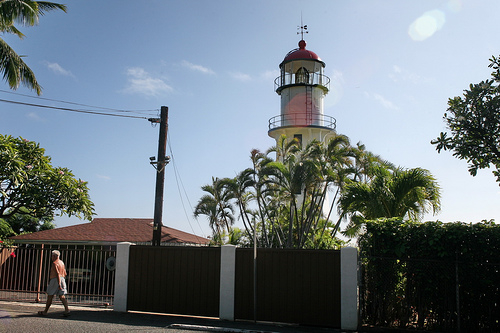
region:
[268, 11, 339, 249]
a light house with a tin red roof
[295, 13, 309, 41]
a weather vane on the top of the light house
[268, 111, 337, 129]
the light house has a balcony around the building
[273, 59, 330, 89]
the light house has a railing around the tower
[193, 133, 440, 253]
a bunch of palm trees are behind the wall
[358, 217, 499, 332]
a hedge next to the wall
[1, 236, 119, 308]
a gate at the front of the house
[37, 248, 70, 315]
a person walking in the front of the house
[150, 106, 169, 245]
a telephone pole on the other side of the fence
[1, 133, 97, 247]
a mango tree in front of the house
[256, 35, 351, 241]
White lighthouse with red domed top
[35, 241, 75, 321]
Old shirtless man walking on sidewalk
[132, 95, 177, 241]
Utility pole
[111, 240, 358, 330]
Privacy fence with white concrette posts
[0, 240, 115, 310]
Closed security gate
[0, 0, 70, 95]
Palm tree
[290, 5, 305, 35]
Metal weather vane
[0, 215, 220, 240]
Red slate roof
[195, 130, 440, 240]
Young palm trees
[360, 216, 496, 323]
Privacy shrubbery approximately eight feet high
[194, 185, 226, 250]
a green healthy tree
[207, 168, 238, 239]
a green healthy tree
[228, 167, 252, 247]
a green healthy tree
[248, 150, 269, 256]
a green healthy tree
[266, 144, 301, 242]
a green healthy tree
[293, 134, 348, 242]
a green healthy tree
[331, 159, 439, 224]
a green healthy tree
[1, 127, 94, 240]
a green healthy tree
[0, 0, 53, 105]
a green healthy tree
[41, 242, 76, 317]
a person is walking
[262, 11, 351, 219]
Red and white light house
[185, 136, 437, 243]
Palm trees behind gate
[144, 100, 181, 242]
Small wooden power pole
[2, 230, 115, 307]
Steel gate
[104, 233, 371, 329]
Large white fence posts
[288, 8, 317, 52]
Weather vein on light house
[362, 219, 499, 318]
Green hedges behind fence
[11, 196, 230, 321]
Building with red roof top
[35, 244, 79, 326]
Person is walking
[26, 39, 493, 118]
Few clouds in sky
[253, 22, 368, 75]
weather vane on top of building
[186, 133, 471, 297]
palm trees in front of light house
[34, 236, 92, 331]
man wearing orange shirt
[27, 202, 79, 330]
man wearing white shorts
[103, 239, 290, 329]
brown and white fence in photo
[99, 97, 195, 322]
telephone pole in photo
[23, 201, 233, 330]
house with red roof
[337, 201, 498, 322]
tall bush next to fence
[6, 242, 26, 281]
something red on fence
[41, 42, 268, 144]
few clouds in sky